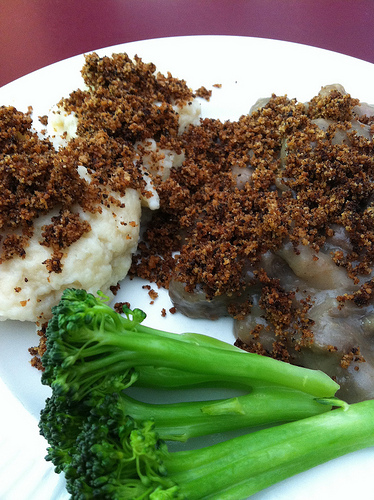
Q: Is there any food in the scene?
A: Yes, there is food.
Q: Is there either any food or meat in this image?
A: Yes, there is food.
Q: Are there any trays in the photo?
A: No, there are no trays.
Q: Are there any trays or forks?
A: No, there are no trays or forks.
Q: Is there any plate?
A: Yes, there is a plate.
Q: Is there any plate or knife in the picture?
A: Yes, there is a plate.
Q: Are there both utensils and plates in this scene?
A: No, there is a plate but no utensils.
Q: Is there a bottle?
A: No, there are no bottles.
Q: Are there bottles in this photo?
A: No, there are no bottles.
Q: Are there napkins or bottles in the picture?
A: No, there are no bottles or napkins.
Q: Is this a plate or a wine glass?
A: This is a plate.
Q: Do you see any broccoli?
A: Yes, there is broccoli.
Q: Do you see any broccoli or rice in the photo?
A: Yes, there is broccoli.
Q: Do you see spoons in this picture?
A: No, there are no spoons.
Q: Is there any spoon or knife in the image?
A: No, there are no spoons or knives.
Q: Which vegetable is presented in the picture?
A: The vegetable is broccoli.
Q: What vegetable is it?
A: The vegetable is broccoli.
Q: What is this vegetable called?
A: That is broccoli.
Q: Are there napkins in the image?
A: No, there are no napkins.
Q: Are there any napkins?
A: No, there are no napkins.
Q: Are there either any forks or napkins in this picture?
A: No, there are no napkins or forks.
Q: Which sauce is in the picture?
A: The sauce is gravy.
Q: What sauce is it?
A: The sauce is gravy.